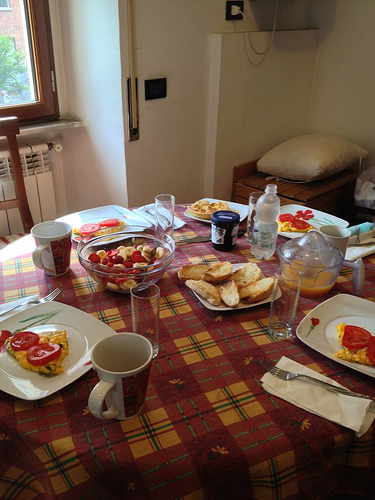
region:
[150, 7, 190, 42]
this is the wall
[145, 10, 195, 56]
the wall is clean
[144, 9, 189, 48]
the wall is white in color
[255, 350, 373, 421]
this is a fork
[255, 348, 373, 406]
the fork is metallic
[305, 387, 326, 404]
this is a serviette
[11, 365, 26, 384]
this is a plate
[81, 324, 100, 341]
the plate is white in color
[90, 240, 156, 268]
these are sliced fruits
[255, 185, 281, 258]
this is a bottle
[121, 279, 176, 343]
clear glass on table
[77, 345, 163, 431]
white mug on table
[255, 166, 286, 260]
clear bottle of water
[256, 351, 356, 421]
fork on white napkin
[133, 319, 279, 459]
red and orange tablecloth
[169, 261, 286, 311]
white plate with toasted bread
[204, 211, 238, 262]
dark glass with jam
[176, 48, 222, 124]
white wall behind table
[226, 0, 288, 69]
white cord on wall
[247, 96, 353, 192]
tan pillow on table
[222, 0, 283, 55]
white cord plugged in to an outlet disappears out of view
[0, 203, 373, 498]
a large round table set with a yellow and red plaid tablecloth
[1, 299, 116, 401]
a square white plate with subtle floral design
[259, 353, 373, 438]
fork partially off a paper napkin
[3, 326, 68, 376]
an egg dish with slices of tomato on top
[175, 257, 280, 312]
slices of toasted bread arranged on a white plate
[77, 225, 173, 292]
yellow and red pieces of chopped fruit in a large glass bowl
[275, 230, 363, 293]
orange liquid in a domed container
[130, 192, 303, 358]
four tall, narrow, empty glasses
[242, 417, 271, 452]
part of a cloth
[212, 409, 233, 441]
part of a cloth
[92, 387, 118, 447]
part of a handle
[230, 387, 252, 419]
part of a cloth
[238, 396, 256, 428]
part fo a line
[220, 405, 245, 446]
part of a table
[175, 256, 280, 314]
a pile of bread on a plate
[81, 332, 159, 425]
an empty coffee mug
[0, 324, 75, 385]
an omelette with tomatoes on top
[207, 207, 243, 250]
an black and white container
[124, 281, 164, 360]
an empty juice glass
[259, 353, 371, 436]
a fork on top of a white napkin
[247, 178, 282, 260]
an open water bottle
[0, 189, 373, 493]
a red, yellow and green patterned tablecloth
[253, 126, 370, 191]
a beige pillow on a wooden chest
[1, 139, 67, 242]
a heater underneath a window